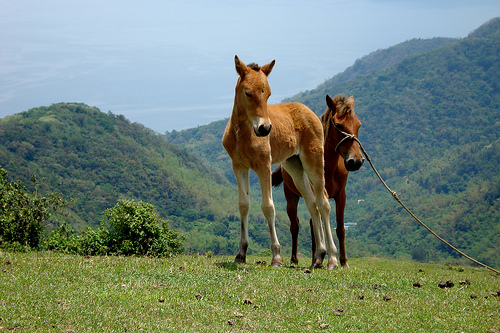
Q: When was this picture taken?
A: During the day.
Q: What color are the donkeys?
A: Brown.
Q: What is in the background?
A: Green mountains.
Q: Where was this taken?
A: In a field.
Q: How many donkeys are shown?
A: Two.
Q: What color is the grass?
A: Green.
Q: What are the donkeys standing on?
A: Grass.